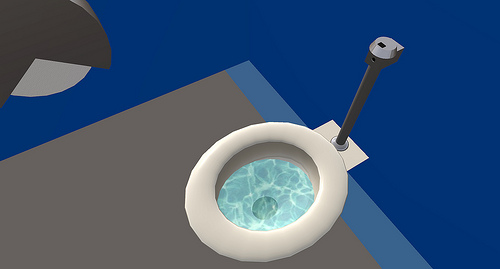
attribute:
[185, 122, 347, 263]
seat — white, animated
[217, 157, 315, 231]
water — blue, white, toilet bowl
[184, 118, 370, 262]
toilet — computer graphic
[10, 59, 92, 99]
paper — animated, white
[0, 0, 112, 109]
dispenser — for paper, gray, large, animated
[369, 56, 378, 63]
sensor — animated, electronic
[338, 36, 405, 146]
post — gray, animated, shiny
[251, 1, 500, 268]
wall — blue, animated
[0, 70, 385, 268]
floor — grey, painted, gray, animated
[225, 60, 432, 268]
line — light blue, empty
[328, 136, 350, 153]
ring — round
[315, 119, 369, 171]
square — white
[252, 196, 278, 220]
hole — animated